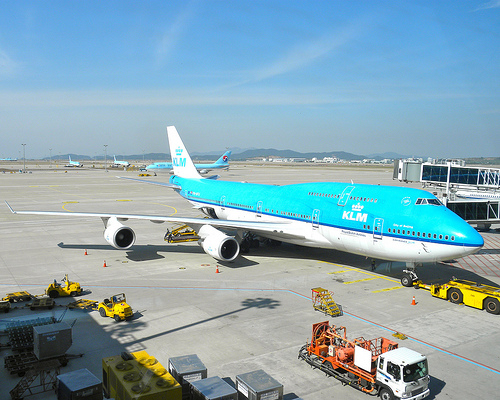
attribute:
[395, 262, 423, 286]
gear — landing gear, deployed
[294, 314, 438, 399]
vehicle — white, orange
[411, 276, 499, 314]
vehicle — yellow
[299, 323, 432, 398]
truck — flatbed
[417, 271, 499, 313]
luggage — yellow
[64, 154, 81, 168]
airplane — one, parked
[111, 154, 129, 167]
airplane — one, parked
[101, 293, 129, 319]
truck — tow, wagon, yellow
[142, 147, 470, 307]
airplane — white, blue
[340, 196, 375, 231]
branding — white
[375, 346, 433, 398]
cab — white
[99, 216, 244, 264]
engines — twin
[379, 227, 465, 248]
windows — row, small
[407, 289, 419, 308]
cone — orange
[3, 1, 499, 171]
sky — blue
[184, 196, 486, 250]
stripe — blue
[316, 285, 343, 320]
stairs — airport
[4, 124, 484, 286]
plane — KLM, blue, white, parked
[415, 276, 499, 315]
carts — yellow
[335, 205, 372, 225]
lettering — white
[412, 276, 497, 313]
truck — yellow, towing, connected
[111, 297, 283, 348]
shadow — long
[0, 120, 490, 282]
airplane — parked, taxied, blue , white, KLM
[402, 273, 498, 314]
luggage carrier — parked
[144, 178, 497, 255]
jet — parked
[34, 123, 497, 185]
distance — far